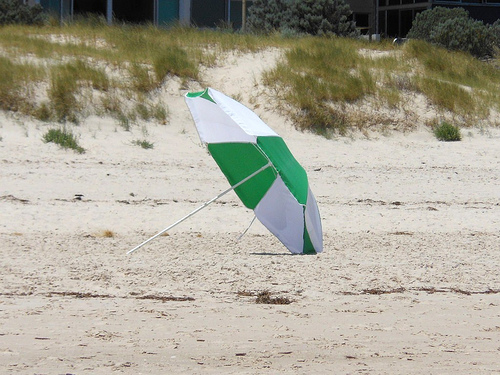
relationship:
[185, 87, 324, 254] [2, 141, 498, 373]
umbrella sitting on beach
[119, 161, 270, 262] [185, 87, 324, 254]
pole of umbrella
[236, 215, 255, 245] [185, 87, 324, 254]
strap hanging from umbrella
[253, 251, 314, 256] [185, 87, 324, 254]
shadow from umbrella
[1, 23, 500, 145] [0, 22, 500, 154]
sand hill with grass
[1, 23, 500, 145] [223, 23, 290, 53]
sand hill with grass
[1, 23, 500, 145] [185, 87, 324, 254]
sand hill behind umbrella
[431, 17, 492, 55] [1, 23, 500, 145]
shrub up on sand hill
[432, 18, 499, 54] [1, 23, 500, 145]
shrub up on sand hill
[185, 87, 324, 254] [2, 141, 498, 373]
umbrella left on beach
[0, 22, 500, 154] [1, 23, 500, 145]
grass covering sand hill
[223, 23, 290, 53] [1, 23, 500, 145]
grass covering sand hill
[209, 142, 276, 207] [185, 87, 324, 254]
panel of umbrella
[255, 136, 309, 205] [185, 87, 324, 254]
panel of umbrella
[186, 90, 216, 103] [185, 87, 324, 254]
panel of umbrella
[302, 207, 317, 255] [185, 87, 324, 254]
panel of umbrella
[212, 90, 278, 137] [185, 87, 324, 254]
panel of umbrella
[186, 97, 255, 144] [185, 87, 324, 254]
panel of umbrella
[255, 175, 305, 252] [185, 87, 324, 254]
panel of umbrella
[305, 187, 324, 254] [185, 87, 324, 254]
panel of umbrella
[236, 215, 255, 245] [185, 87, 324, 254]
strap to close umbrella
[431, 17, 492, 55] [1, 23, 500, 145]
shrub near sand hill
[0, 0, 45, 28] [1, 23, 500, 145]
tree at top of sand hill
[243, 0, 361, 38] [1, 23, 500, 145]
tree at top of sand hill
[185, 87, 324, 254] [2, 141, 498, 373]
umbrella laying on beach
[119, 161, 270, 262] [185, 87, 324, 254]
pole for umbrella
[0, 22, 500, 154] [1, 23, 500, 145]
grass growing on sand hill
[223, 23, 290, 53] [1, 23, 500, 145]
grass growing on sand hill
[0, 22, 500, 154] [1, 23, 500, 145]
grass growing on side of sand hill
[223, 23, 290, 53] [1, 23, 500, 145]
grass growing on side of sand hill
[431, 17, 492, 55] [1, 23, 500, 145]
shrub behind sand hill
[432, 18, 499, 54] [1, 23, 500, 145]
shrub behind sand hill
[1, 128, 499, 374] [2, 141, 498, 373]
sand spread out on beach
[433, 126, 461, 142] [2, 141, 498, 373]
grass growing on beach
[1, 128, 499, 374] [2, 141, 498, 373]
sand laying on beach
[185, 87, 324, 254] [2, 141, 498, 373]
umbrella lying on beach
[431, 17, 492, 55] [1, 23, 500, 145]
shrub on top of sand hill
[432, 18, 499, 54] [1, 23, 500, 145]
shrub on top of sand hill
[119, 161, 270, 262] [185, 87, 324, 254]
pole to umbrella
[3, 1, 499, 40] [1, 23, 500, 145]
building above sand hill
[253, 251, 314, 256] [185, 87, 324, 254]
shadow cast by umbrella